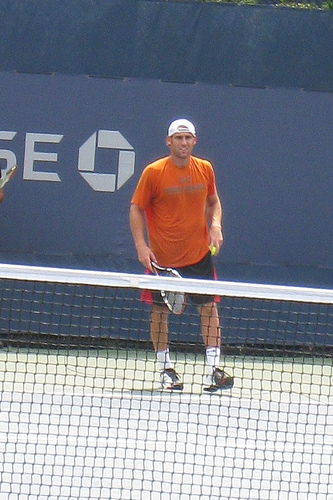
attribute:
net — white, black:
[2, 262, 331, 492]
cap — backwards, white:
[164, 115, 201, 141]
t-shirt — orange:
[128, 154, 219, 272]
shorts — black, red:
[133, 248, 223, 309]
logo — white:
[2, 123, 138, 198]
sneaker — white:
[156, 362, 187, 396]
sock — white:
[202, 346, 223, 372]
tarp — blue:
[3, 1, 331, 353]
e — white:
[22, 129, 64, 188]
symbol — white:
[74, 128, 139, 197]